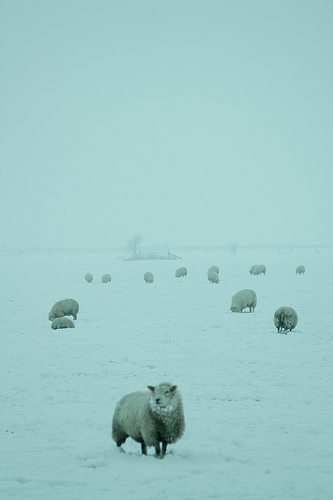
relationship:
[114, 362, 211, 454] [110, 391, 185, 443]
sheep with wool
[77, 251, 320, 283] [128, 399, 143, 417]
sheep has wool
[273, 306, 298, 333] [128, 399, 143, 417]
sheep has wool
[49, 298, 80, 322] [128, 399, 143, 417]
sheep has wool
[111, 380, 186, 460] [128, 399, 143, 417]
sheep has wool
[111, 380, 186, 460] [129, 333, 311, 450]
sheep on snow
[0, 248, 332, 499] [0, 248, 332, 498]
snow covering ground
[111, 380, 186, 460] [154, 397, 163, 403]
sheep has nose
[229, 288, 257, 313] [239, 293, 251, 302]
sheep has wool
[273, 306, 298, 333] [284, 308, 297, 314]
sheep has wool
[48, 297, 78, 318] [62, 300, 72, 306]
sheep has wool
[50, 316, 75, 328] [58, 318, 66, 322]
sheep has wool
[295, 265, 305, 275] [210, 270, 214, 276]
sheep has wool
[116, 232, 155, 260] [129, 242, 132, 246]
tree has branch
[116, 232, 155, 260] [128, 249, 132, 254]
tree has branch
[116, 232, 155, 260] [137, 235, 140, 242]
tree has branch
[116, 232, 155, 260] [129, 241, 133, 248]
tree has branch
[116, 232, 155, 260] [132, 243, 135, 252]
tree has branch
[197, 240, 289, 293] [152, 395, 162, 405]
sheep has nose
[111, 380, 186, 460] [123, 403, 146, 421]
sheep has wool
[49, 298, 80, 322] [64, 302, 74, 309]
sheep has wool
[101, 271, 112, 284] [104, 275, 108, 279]
sheep has wool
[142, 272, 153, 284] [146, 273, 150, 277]
sheep has wool